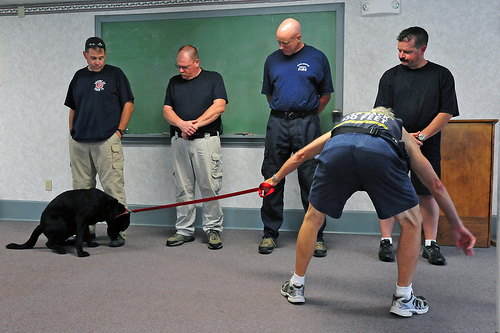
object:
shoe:
[388, 294, 431, 318]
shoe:
[165, 232, 199, 246]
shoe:
[204, 230, 224, 250]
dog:
[4, 188, 131, 257]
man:
[261, 107, 478, 317]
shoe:
[422, 240, 447, 266]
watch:
[113, 127, 127, 136]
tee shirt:
[259, 44, 334, 111]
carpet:
[1, 218, 496, 331]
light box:
[356, 0, 404, 15]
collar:
[111, 208, 130, 219]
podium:
[423, 118, 499, 249]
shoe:
[277, 279, 307, 305]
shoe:
[377, 237, 396, 263]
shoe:
[255, 232, 279, 255]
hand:
[260, 177, 278, 193]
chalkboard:
[93, 2, 344, 147]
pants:
[170, 130, 225, 237]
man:
[368, 25, 458, 265]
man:
[256, 16, 334, 258]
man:
[160, 45, 229, 250]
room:
[1, 2, 497, 333]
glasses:
[174, 58, 197, 70]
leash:
[132, 183, 277, 213]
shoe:
[308, 239, 329, 258]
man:
[64, 36, 134, 241]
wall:
[2, 0, 498, 242]